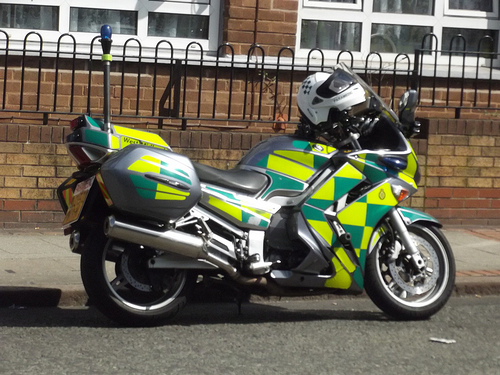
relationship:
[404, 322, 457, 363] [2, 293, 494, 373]
trash on road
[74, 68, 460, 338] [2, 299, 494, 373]
bike on street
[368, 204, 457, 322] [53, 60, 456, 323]
fronttire of bike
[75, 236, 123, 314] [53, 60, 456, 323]
tire of bike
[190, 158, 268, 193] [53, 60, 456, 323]
seat on bike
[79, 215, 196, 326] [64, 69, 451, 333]
tire on motorcycle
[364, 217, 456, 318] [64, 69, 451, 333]
tire on motorcycle